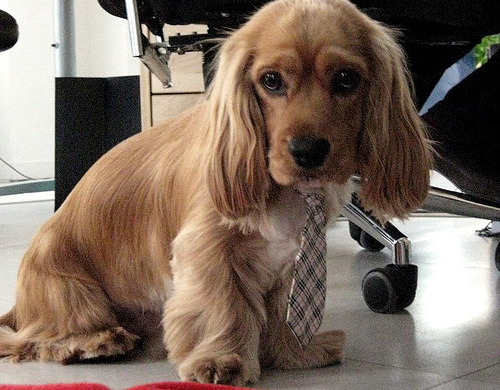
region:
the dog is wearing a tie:
[257, 148, 379, 375]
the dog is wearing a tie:
[282, 174, 340, 352]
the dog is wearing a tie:
[263, 192, 349, 366]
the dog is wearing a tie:
[300, 190, 335, 357]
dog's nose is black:
[279, 130, 330, 176]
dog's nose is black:
[280, 127, 340, 179]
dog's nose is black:
[276, 128, 334, 189]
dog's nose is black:
[286, 124, 336, 179]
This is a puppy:
[10, 10, 460, 372]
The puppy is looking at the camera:
[217, 3, 418, 210]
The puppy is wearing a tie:
[280, 168, 341, 337]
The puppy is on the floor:
[9, 32, 487, 379]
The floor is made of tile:
[332, 262, 490, 380]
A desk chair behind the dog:
[112, 11, 498, 323]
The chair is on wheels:
[354, 205, 499, 323]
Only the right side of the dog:
[34, 36, 376, 371]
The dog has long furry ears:
[200, 29, 435, 226]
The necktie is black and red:
[285, 200, 344, 362]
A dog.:
[8, 3, 433, 388]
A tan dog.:
[10, 0, 427, 389]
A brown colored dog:
[6, 5, 438, 387]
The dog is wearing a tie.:
[10, 4, 427, 388]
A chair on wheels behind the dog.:
[121, 5, 493, 302]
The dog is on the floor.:
[9, 3, 434, 388]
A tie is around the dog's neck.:
[8, 5, 440, 382]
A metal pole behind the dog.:
[43, 0, 86, 87]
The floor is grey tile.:
[13, 191, 492, 388]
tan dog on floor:
[2, 0, 443, 387]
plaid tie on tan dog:
[279, 183, 337, 359]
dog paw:
[168, 353, 265, 388]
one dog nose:
[281, 135, 339, 177]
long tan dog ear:
[196, 40, 278, 227]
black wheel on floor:
[353, 253, 436, 321]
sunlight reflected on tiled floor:
[397, 212, 497, 331]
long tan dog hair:
[117, 176, 155, 254]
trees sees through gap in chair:
[450, 22, 498, 79]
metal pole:
[47, 0, 84, 83]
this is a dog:
[31, 2, 497, 381]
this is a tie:
[280, 175, 343, 357]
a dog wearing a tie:
[23, 1, 499, 365]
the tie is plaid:
[275, 159, 342, 346]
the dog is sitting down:
[18, 1, 459, 376]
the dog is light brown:
[12, 7, 492, 383]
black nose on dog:
[280, 122, 324, 184]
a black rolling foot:
[356, 233, 423, 333]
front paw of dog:
[149, 307, 274, 387]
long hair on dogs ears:
[168, 10, 445, 252]